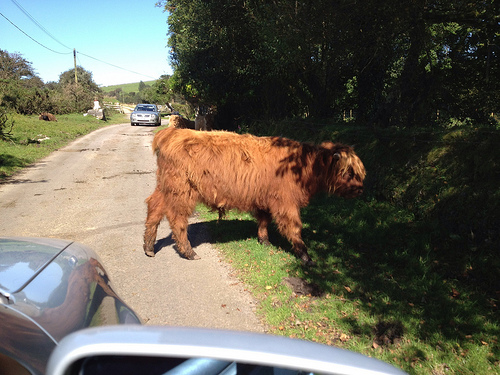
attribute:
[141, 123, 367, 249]
cow — brown, shaggy, vbrown, v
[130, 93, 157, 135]
car — silver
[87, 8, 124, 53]
sky — blue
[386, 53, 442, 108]
tree — green